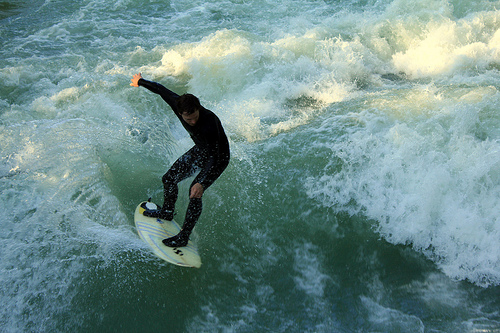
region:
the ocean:
[35, 18, 473, 310]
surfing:
[17, 13, 431, 331]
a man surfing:
[72, 51, 238, 291]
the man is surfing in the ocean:
[111, 46, 236, 285]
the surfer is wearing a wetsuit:
[99, 58, 236, 284]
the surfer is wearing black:
[128, 64, 235, 294]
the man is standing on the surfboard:
[115, 63, 246, 275]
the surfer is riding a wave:
[66, 29, 248, 289]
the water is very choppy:
[64, 26, 455, 292]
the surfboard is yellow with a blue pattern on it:
[124, 176, 212, 290]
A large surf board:
[137, 197, 203, 281]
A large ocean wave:
[251, 143, 376, 298]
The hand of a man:
[125, 71, 149, 94]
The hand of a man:
[174, 176, 213, 205]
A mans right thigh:
[156, 154, 203, 186]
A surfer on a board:
[106, 31, 230, 273]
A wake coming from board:
[62, 122, 147, 235]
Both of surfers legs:
[145, 177, 205, 260]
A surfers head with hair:
[170, 90, 203, 127]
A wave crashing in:
[189, 18, 323, 109]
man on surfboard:
[121, 64, 235, 279]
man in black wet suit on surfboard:
[126, 63, 233, 276]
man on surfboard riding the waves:
[120, 62, 234, 282]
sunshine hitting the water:
[153, 11, 495, 115]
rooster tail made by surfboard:
[35, 117, 130, 256]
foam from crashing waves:
[366, 11, 496, 280]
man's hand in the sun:
[120, 67, 150, 89]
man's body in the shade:
[129, 63, 233, 283]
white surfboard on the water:
[131, 195, 203, 270]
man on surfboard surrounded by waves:
[5, 3, 496, 327]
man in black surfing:
[117, 68, 235, 273]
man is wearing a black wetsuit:
[122, 70, 239, 274]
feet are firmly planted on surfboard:
[131, 193, 219, 286]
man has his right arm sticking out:
[118, 70, 219, 127]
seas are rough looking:
[255, 64, 477, 246]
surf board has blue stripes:
[132, 195, 218, 282]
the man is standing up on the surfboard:
[111, 68, 247, 293]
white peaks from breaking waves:
[318, 115, 481, 284]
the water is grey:
[264, 146, 374, 321]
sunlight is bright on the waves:
[354, 62, 475, 114]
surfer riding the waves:
[40, 17, 476, 318]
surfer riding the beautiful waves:
[15, 25, 426, 295]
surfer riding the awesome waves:
[51, 56, 396, 296]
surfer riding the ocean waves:
[15, 35, 420, 295]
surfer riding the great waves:
[55, 37, 381, 297]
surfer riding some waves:
[52, 16, 317, 298]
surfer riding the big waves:
[50, 30, 400, 295]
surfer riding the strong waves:
[36, 37, 371, 303]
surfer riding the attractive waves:
[10, 27, 355, 292]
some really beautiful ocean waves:
[241, 40, 478, 296]